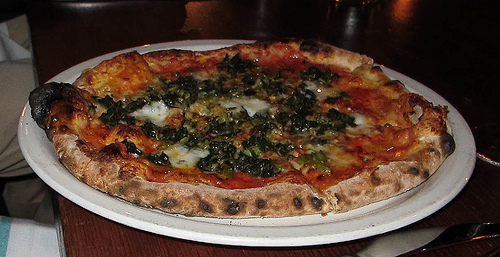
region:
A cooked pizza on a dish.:
[35, 40, 455, 215]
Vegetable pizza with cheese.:
[35, 35, 460, 217]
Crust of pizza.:
[160, 180, 335, 215]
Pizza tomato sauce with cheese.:
[105, 76, 390, 171]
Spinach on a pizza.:
[200, 140, 275, 180]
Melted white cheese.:
[210, 90, 270, 105]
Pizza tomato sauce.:
[250, 50, 340, 75]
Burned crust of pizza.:
[20, 75, 75, 121]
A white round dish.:
[11, 200, 467, 245]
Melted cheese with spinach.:
[161, 137, 271, 168]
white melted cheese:
[130, 97, 170, 130]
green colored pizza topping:
[271, 93, 346, 136]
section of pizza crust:
[375, 137, 442, 210]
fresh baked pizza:
[28, 36, 451, 210]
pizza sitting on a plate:
[13, 25, 479, 251]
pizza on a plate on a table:
[3, 53, 490, 255]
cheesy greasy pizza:
[36, 31, 444, 216]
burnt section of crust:
[23, 70, 91, 142]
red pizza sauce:
[122, 133, 159, 167]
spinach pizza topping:
[180, 109, 245, 159]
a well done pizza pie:
[31, 38, 462, 213]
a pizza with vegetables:
[30, 34, 457, 219]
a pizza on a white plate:
[15, 36, 477, 247]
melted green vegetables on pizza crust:
[116, 66, 378, 178]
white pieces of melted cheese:
[133, 91, 280, 176]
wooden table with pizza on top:
[60, 33, 495, 254]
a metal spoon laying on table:
[416, 216, 498, 254]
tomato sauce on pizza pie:
[94, 73, 412, 182]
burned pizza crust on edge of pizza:
[26, 77, 83, 137]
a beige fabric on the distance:
[3, 60, 33, 180]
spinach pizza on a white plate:
[38, 21, 422, 247]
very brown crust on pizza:
[131, 158, 443, 222]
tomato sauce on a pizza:
[355, 87, 430, 178]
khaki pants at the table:
[0, 50, 41, 136]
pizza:
[32, 32, 468, 215]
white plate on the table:
[0, 36, 468, 227]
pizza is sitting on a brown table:
[18, 5, 323, 251]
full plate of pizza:
[37, 25, 475, 233]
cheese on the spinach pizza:
[157, 115, 213, 180]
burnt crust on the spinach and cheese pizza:
[26, 75, 85, 140]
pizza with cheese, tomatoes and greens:
[41, 35, 457, 218]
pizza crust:
[143, 177, 315, 212]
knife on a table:
[370, 215, 491, 255]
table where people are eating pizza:
[68, 202, 124, 254]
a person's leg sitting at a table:
[2, 57, 48, 229]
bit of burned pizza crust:
[28, 79, 76, 124]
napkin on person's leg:
[3, 217, 58, 255]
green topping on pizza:
[214, 124, 266, 174]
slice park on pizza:
[287, 166, 348, 221]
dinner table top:
[55, 7, 457, 38]